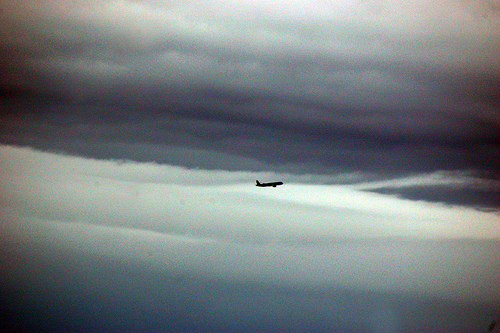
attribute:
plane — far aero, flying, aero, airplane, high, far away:
[254, 176, 285, 189]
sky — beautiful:
[2, 2, 499, 332]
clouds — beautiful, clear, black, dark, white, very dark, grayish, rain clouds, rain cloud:
[4, 2, 498, 332]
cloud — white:
[1, 150, 498, 260]